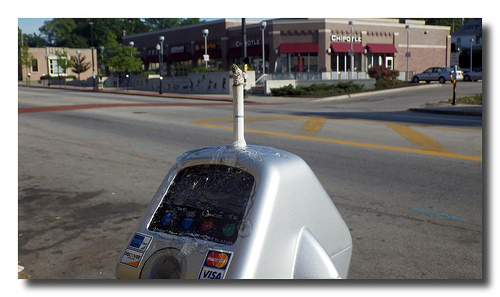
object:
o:
[346, 37, 351, 42]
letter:
[331, 35, 336, 42]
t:
[352, 36, 355, 42]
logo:
[196, 248, 234, 280]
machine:
[114, 144, 354, 282]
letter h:
[337, 35, 342, 41]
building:
[17, 47, 97, 82]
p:
[342, 36, 347, 42]